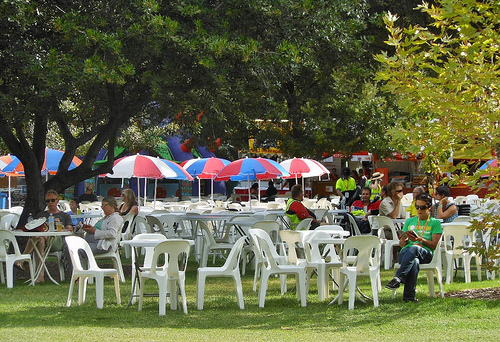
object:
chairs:
[0, 223, 382, 316]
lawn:
[0, 242, 500, 342]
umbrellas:
[0, 146, 332, 182]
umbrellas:
[95, 155, 195, 185]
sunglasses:
[415, 203, 432, 210]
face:
[415, 199, 427, 218]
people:
[284, 168, 459, 302]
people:
[13, 188, 139, 284]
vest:
[284, 198, 312, 230]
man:
[285, 184, 329, 230]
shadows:
[1, 291, 499, 332]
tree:
[0, 0, 500, 276]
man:
[385, 193, 442, 303]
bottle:
[49, 213, 55, 232]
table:
[10, 231, 72, 287]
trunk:
[1, 83, 151, 267]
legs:
[65, 274, 122, 309]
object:
[396, 230, 418, 241]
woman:
[65, 196, 124, 284]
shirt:
[399, 215, 443, 256]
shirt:
[79, 193, 99, 204]